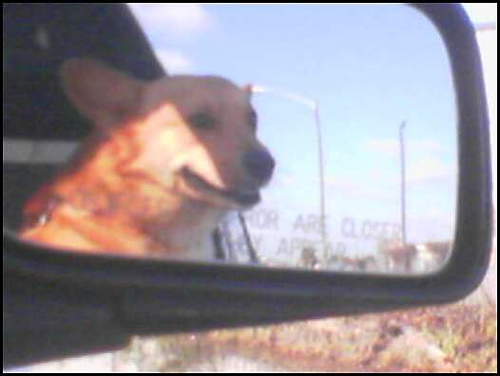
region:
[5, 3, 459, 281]
rear view mirror on the drivers side of the car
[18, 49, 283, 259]
dog reflection in the rear view mirror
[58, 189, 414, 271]
OBJECTS IN MIRROR ARE CLOSER THEN THEY APPEAR is what is printed on mirror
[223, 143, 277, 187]
the dogs nose is black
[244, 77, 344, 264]
the street light is on a silver pole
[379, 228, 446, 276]
a building on the side of the road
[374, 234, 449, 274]
the building is white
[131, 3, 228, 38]
the cloud in the sky is white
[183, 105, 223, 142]
the dogs eye is brown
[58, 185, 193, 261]
the dogs collar is red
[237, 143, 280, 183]
Dog nose is black.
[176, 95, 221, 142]
Dog's eye is black.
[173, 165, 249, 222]
Dog's mouth is black.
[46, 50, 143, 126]
Brown ear of dog.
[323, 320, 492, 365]
Green and brown weeds.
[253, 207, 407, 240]
Lettering in the distance.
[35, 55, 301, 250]
Golden brownish looking dog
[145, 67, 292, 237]
Dog is looking out window.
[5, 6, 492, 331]
Rearview mirror dog is looking out of.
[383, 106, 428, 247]
Street light pole in the distance.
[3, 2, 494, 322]
mirror on a car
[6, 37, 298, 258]
a brown dog reflected on a mirror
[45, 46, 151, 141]
ear of dog is big and pointy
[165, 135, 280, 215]
the dog has his mouth open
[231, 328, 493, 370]
grass next to car is dry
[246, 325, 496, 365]
grass next to car is color brown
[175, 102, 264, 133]
eyes of brown dog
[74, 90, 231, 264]
sunshine on right side of a dog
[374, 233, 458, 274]
a building is reflected on lower side of mirror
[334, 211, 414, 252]
letter "closer" on a mirror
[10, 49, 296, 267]
dog in a rear view mirror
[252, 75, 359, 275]
street light in reflection of mirror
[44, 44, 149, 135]
right ear of a dog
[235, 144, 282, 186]
nose of a dog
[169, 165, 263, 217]
mouth of a dog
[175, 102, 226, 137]
right eye of a dog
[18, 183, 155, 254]
collar on a dog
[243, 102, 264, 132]
left eye of dog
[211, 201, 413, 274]
sticker on rearview mirror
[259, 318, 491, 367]
grasses along side of road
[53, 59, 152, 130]
this is a dog ear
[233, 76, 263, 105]
this is an ear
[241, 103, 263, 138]
this is an eye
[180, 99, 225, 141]
a dog's brown eye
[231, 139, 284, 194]
a black dog nose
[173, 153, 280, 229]
a dog's little mouth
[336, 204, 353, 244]
the gray letter C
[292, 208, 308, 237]
the gray letter A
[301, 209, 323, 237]
the gray letter R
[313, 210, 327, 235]
the gray letter E